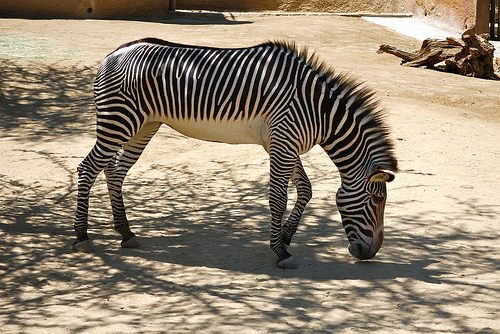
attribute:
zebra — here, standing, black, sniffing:
[74, 37, 399, 270]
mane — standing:
[272, 38, 398, 175]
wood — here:
[377, 25, 499, 81]